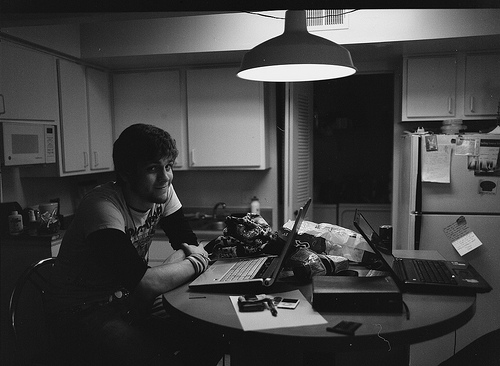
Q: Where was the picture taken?
A: It was taken at the kitchen.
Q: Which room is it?
A: It is a kitchen.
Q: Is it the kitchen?
A: Yes, it is the kitchen.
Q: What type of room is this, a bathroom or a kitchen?
A: It is a kitchen.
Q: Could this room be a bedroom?
A: No, it is a kitchen.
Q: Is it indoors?
A: Yes, it is indoors.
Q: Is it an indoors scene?
A: Yes, it is indoors.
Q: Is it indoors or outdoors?
A: It is indoors.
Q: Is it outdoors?
A: No, it is indoors.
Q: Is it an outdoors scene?
A: No, it is indoors.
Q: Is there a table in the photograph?
A: Yes, there is a table.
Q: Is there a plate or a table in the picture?
A: Yes, there is a table.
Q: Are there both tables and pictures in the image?
A: No, there is a table but no pictures.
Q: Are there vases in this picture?
A: No, there are no vases.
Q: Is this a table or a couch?
A: This is a table.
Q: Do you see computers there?
A: Yes, there is a computer.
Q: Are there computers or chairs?
A: Yes, there is a computer.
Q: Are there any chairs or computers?
A: Yes, there is a computer.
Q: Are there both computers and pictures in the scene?
A: No, there is a computer but no pictures.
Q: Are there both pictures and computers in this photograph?
A: No, there is a computer but no pictures.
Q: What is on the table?
A: The computer is on the table.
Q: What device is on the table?
A: The device is a computer.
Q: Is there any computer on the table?
A: Yes, there is a computer on the table.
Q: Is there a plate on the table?
A: No, there is a computer on the table.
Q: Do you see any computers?
A: Yes, there is a computer.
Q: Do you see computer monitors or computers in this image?
A: Yes, there is a computer.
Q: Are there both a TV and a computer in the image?
A: No, there is a computer but no televisions.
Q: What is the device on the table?
A: The device is a computer.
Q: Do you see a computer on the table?
A: Yes, there is a computer on the table.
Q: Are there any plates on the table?
A: No, there is a computer on the table.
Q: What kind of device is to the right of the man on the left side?
A: The device is a computer.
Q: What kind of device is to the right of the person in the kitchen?
A: The device is a computer.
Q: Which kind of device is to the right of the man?
A: The device is a computer.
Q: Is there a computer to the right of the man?
A: Yes, there is a computer to the right of the man.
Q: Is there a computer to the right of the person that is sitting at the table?
A: Yes, there is a computer to the right of the man.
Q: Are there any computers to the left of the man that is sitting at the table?
A: No, the computer is to the right of the man.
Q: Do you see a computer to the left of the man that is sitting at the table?
A: No, the computer is to the right of the man.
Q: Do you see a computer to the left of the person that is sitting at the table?
A: No, the computer is to the right of the man.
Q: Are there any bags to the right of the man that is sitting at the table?
A: No, there is a computer to the right of the man.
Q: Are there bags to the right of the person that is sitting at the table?
A: No, there is a computer to the right of the man.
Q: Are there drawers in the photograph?
A: No, there are no drawers.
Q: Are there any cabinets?
A: Yes, there is a cabinet.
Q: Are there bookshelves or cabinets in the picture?
A: Yes, there is a cabinet.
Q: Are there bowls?
A: No, there are no bowls.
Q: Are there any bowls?
A: No, there are no bowls.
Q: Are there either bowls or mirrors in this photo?
A: No, there are no bowls or mirrors.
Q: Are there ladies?
A: No, there are no ladies.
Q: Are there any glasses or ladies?
A: No, there are no ladies or glasses.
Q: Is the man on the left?
A: Yes, the man is on the left of the image.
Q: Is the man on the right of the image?
A: No, the man is on the left of the image.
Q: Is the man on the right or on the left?
A: The man is on the left of the image.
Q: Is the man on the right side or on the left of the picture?
A: The man is on the left of the image.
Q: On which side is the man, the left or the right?
A: The man is on the left of the image.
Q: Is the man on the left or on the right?
A: The man is on the left of the image.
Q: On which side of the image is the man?
A: The man is on the left of the image.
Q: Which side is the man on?
A: The man is on the left of the image.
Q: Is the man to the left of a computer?
A: Yes, the man is to the left of a computer.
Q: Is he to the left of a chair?
A: No, the man is to the left of a computer.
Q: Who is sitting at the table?
A: The man is sitting at the table.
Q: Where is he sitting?
A: The man is sitting at the table.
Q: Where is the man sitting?
A: The man is sitting at the table.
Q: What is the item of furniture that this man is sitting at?
A: The piece of furniture is a table.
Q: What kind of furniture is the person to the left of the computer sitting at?
A: The man is sitting at the table.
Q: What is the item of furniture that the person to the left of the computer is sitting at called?
A: The piece of furniture is a table.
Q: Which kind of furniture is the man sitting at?
A: The man is sitting at the table.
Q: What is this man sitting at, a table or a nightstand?
A: The man is sitting at a table.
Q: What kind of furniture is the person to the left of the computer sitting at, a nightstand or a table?
A: The man is sitting at a table.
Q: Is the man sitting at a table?
A: Yes, the man is sitting at a table.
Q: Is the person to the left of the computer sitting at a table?
A: Yes, the man is sitting at a table.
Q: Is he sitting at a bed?
A: No, the man is sitting at a table.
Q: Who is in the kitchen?
A: The man is in the kitchen.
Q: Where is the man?
A: The man is in the kitchen.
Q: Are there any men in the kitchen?
A: Yes, there is a man in the kitchen.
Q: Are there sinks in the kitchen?
A: No, there is a man in the kitchen.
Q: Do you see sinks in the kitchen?
A: No, there is a man in the kitchen.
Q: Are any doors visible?
A: Yes, there is a door.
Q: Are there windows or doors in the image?
A: Yes, there is a door.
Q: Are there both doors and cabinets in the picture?
A: Yes, there are both a door and a cabinet.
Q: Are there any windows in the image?
A: No, there are no windows.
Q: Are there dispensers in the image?
A: No, there are no dispensers.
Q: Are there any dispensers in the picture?
A: No, there are no dispensers.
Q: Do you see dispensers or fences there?
A: No, there are no dispensers or fences.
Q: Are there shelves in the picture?
A: No, there are no shelves.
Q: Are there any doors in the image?
A: Yes, there is a door.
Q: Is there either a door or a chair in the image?
A: Yes, there is a door.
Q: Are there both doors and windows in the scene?
A: No, there is a door but no windows.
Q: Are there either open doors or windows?
A: Yes, there is an open door.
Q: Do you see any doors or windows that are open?
A: Yes, the door is open.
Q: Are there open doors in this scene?
A: Yes, there is an open door.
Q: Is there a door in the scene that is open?
A: Yes, there is an open door.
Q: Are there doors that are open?
A: Yes, there is a door that is open.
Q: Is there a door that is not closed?
A: Yes, there is a open door.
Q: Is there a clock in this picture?
A: No, there are no clocks.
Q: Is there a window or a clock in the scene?
A: No, there are no clocks or windows.